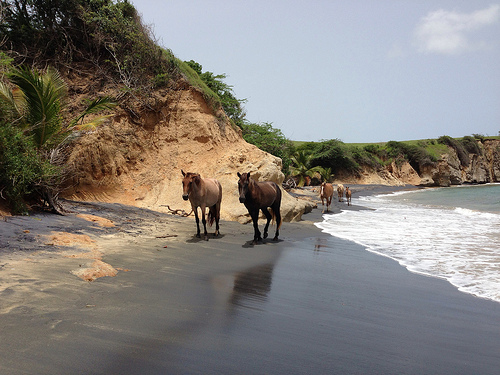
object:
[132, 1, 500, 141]
sky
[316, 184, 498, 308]
water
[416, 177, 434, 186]
rock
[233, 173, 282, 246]
horse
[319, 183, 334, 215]
horse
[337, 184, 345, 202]
horse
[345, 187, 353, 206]
horse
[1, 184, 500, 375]
beach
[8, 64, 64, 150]
plant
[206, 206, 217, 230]
tail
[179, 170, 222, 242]
horse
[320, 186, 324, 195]
marking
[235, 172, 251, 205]
face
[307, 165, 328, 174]
leaves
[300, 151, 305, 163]
leaves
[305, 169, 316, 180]
leaves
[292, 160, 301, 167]
leaves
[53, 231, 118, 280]
sand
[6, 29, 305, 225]
cliff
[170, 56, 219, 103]
grass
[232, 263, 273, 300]
reflection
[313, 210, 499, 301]
foam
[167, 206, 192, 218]
branch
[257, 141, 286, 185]
rock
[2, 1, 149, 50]
tree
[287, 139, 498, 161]
hill